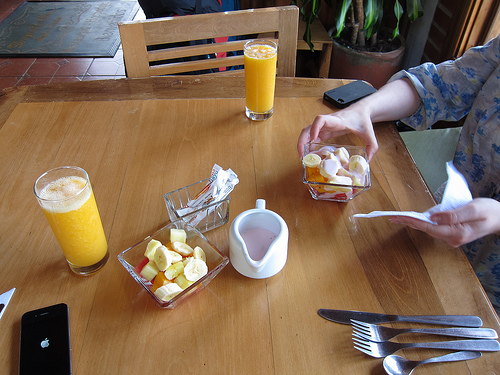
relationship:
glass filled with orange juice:
[245, 39, 277, 121] [39, 175, 109, 279]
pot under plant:
[330, 24, 407, 84] [300, 1, 424, 50]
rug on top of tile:
[1, 1, 143, 56] [22, 56, 95, 76]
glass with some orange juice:
[245, 39, 277, 121] [39, 175, 109, 279]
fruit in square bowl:
[305, 145, 368, 186] [304, 141, 373, 205]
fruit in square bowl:
[137, 231, 208, 302] [115, 216, 229, 311]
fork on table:
[349, 318, 498, 341] [2, 78, 500, 374]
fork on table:
[349, 340, 499, 359] [2, 78, 500, 374]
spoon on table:
[383, 348, 481, 374] [2, 78, 500, 374]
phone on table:
[18, 302, 68, 374] [2, 78, 500, 374]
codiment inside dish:
[178, 163, 234, 217] [163, 175, 230, 234]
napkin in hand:
[443, 162, 469, 218] [390, 199, 500, 249]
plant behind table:
[300, 1, 424, 50] [2, 78, 500, 374]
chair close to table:
[118, 6, 299, 82] [2, 78, 500, 374]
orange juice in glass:
[39, 175, 109, 279] [245, 39, 277, 121]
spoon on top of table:
[383, 348, 481, 374] [2, 78, 500, 374]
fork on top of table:
[349, 318, 498, 341] [2, 78, 500, 374]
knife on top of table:
[317, 308, 483, 329] [2, 78, 500, 374]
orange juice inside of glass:
[39, 175, 109, 279] [245, 39, 277, 121]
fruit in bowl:
[305, 145, 368, 186] [304, 141, 373, 205]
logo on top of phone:
[40, 338, 49, 349] [323, 80, 378, 106]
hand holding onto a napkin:
[390, 199, 500, 249] [443, 162, 469, 218]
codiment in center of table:
[178, 163, 234, 217] [2, 78, 500, 374]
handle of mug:
[255, 199, 266, 210] [232, 198, 290, 278]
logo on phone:
[40, 338, 49, 349] [18, 302, 68, 374]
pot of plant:
[330, 24, 407, 84] [300, 1, 424, 50]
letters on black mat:
[13, 10, 50, 48] [1, 1, 143, 56]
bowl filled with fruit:
[115, 216, 229, 311] [305, 145, 368, 186]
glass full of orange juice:
[245, 39, 277, 121] [39, 175, 109, 279]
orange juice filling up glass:
[39, 175, 109, 279] [245, 39, 277, 121]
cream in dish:
[211, 163, 220, 183] [163, 175, 230, 234]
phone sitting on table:
[323, 80, 378, 106] [2, 78, 500, 374]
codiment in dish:
[178, 163, 234, 217] [163, 175, 230, 234]